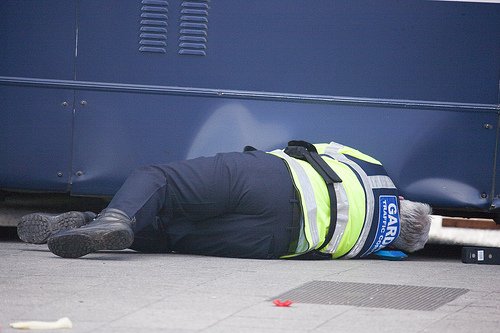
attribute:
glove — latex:
[10, 314, 71, 328]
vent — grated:
[272, 279, 472, 313]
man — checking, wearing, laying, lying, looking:
[15, 138, 435, 266]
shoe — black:
[15, 200, 131, 261]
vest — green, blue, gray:
[280, 132, 397, 261]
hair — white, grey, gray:
[398, 194, 431, 256]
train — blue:
[1, 2, 499, 220]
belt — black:
[291, 133, 343, 262]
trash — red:
[271, 290, 298, 309]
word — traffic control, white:
[374, 196, 401, 259]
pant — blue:
[93, 147, 291, 267]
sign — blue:
[382, 197, 404, 249]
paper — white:
[5, 307, 76, 333]